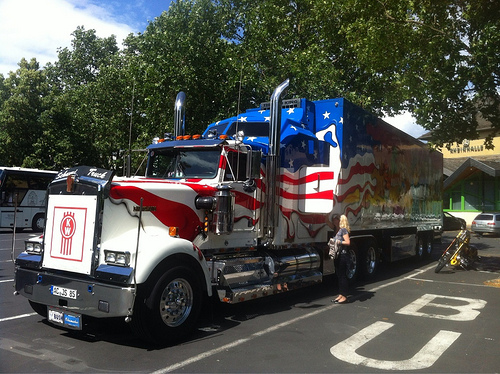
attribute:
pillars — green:
[447, 184, 464, 212]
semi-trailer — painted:
[209, 91, 455, 259]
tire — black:
[434, 255, 452, 273]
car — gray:
[468, 207, 498, 232]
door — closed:
[220, 137, 261, 234]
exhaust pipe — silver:
[261, 79, 292, 243]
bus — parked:
[2, 149, 79, 235]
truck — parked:
[29, 55, 456, 314]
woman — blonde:
[332, 211, 355, 306]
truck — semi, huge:
[13, 65, 447, 352]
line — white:
[206, 315, 285, 354]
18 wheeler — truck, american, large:
[10, 75, 445, 341]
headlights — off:
[94, 252, 129, 267]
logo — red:
[58, 212, 75, 254]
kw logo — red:
[58, 211, 76, 253]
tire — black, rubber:
[130, 253, 210, 353]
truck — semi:
[55, 80, 474, 340]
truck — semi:
[42, 112, 447, 332]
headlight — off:
[104, 248, 132, 268]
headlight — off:
[25, 241, 44, 254]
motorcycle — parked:
[433, 223, 483, 275]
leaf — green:
[21, 67, 35, 85]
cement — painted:
[167, 259, 484, 372]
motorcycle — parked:
[432, 222, 479, 276]